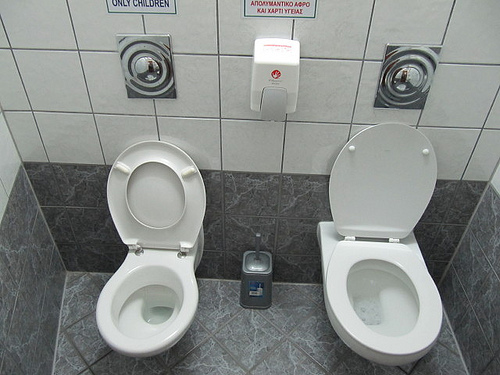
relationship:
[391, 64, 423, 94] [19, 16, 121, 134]
button on wall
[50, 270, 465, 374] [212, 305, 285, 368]
floor made of tile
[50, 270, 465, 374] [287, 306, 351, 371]
floor made of tile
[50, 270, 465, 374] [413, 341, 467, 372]
floor made of tile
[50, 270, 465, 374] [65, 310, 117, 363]
floor made of tile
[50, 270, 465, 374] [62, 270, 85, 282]
floor made of tile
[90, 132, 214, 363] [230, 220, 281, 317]
toilet has cleaner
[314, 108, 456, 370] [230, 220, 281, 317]
toilet has cleaner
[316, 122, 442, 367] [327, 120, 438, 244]
toilet with lid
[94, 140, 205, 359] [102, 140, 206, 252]
toilet with lid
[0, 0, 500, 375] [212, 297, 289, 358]
tile with floor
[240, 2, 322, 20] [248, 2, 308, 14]
sign with lettering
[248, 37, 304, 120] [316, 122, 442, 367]
dispenser between toilet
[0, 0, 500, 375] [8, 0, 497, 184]
tile on wall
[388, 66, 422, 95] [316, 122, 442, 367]
button behind toilet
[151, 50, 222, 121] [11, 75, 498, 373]
tile in bathroom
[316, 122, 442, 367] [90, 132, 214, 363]
toilet by toilet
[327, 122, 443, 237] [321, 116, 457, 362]
lid on toilet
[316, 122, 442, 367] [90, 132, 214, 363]
toilet next to toilet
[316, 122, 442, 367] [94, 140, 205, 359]
toilet next to toilet